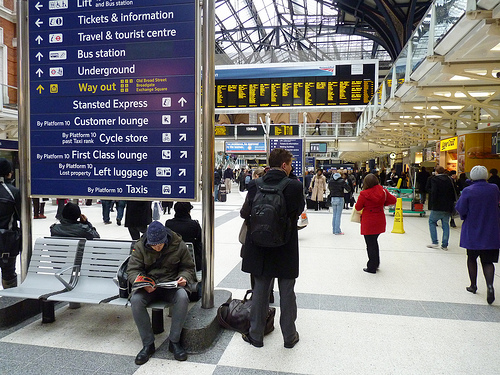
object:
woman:
[355, 173, 397, 273]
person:
[125, 220, 194, 366]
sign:
[440, 136, 458, 152]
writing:
[442, 140, 454, 150]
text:
[77, 64, 136, 77]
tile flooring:
[0, 193, 499, 375]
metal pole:
[193, 0, 214, 311]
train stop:
[0, 0, 497, 375]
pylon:
[391, 198, 406, 234]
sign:
[394, 207, 403, 223]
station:
[0, 0, 500, 375]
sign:
[87, 184, 187, 195]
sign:
[58, 162, 186, 180]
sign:
[37, 148, 189, 161]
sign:
[34, 114, 187, 128]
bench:
[0, 237, 197, 333]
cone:
[390, 198, 405, 235]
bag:
[217, 290, 275, 336]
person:
[239, 146, 304, 349]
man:
[125, 222, 195, 366]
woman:
[454, 165, 500, 304]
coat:
[456, 181, 498, 250]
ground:
[0, 182, 500, 374]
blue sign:
[27, 0, 200, 199]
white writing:
[93, 166, 148, 178]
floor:
[0, 181, 500, 374]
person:
[453, 165, 500, 306]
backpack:
[247, 176, 293, 248]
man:
[239, 147, 305, 348]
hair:
[267, 148, 293, 167]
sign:
[27, 0, 194, 199]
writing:
[111, 98, 149, 161]